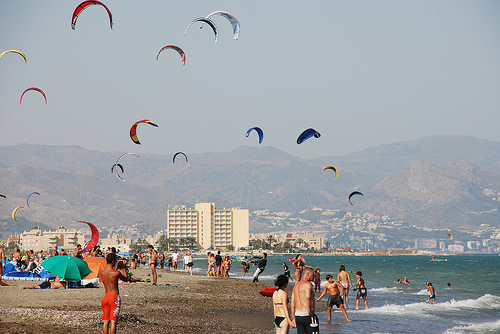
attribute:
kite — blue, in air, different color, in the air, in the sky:
[244, 123, 266, 149]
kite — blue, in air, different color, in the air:
[294, 126, 323, 147]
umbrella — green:
[38, 252, 94, 285]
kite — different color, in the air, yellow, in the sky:
[320, 162, 340, 181]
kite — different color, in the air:
[126, 116, 162, 147]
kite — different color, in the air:
[69, 0, 117, 33]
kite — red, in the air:
[17, 85, 51, 109]